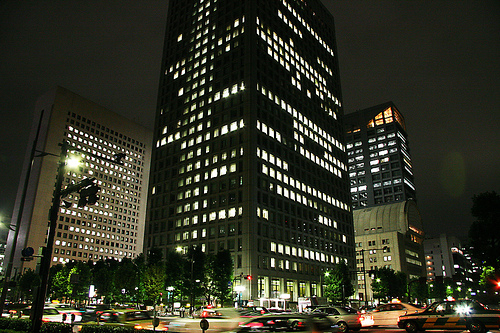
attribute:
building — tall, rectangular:
[21, 97, 152, 303]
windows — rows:
[64, 142, 137, 249]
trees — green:
[6, 241, 248, 318]